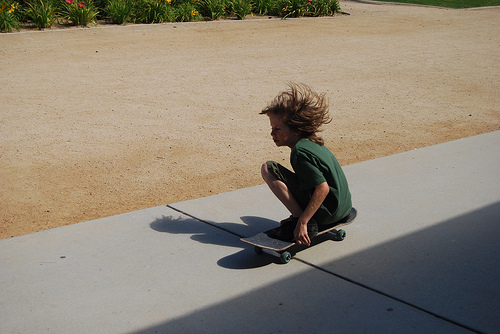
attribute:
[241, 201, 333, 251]
skateboard — black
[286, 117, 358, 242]
t-shirt — green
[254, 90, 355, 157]
hair — brown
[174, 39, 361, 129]
hair — long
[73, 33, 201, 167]
dirt — brown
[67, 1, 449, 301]
photo — one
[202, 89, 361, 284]
boy — blond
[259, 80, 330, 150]
hair — flying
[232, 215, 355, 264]
skateboard — black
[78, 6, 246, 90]
greenery — background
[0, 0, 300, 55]
flowers — background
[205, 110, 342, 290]
boy — crounching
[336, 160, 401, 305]
concrete slab — grey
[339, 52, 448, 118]
dirt — sandy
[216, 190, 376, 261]
skateboard — black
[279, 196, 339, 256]
shoes — black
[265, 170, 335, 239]
shorts — green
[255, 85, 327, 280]
boy — young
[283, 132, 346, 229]
shirt — green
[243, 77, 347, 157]
hair — blowing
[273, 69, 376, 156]
hair — long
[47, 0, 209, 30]
plants — distant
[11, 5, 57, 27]
plant — small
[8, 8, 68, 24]
plant — small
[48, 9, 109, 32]
plant — small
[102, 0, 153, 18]
plant — small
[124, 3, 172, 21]
plant — small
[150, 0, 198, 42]
plant — small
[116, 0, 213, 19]
plant — small